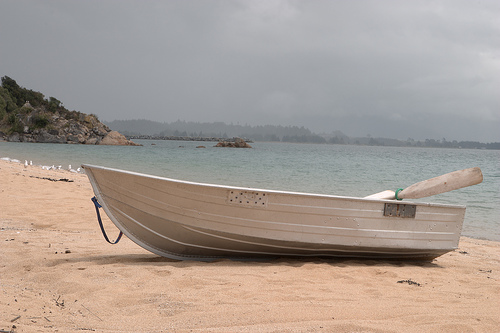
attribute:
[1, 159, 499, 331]
beach — sandy, light brown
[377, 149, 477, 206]
oar — white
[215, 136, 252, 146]
outcropping — rocky, small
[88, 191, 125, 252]
tether — blue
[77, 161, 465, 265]
boat — aluminum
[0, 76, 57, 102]
trees — green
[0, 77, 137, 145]
hillside — rocky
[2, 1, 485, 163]
sky — cloudy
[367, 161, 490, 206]
oar — wood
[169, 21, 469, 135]
sky — cloudy, gray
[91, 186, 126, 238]
tether — hanging down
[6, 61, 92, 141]
trees — group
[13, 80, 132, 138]
hillside — rocky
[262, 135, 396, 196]
island — small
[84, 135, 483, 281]
canoe — aluminum